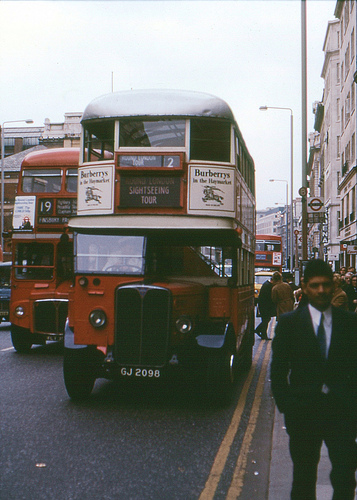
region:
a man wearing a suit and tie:
[287, 257, 348, 396]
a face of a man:
[308, 274, 330, 306]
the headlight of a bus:
[173, 313, 192, 336]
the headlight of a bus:
[86, 307, 105, 328]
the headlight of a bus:
[13, 304, 26, 317]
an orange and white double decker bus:
[67, 95, 247, 402]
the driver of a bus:
[97, 235, 146, 275]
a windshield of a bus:
[72, 230, 241, 278]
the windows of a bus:
[81, 116, 234, 162]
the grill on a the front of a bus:
[109, 284, 172, 369]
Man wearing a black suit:
[261, 248, 355, 498]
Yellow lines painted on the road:
[208, 400, 251, 498]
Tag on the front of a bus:
[113, 359, 162, 385]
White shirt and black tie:
[305, 301, 339, 357]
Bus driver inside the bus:
[67, 228, 148, 278]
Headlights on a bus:
[87, 300, 196, 338]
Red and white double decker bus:
[59, 102, 261, 409]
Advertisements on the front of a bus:
[76, 156, 237, 223]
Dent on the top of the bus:
[188, 104, 227, 115]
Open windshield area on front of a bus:
[79, 115, 122, 166]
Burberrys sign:
[188, 162, 239, 218]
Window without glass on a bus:
[81, 119, 119, 163]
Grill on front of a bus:
[106, 284, 179, 366]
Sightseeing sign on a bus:
[115, 166, 185, 209]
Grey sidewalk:
[276, 451, 288, 478]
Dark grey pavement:
[98, 428, 149, 482]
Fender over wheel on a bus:
[190, 313, 234, 350]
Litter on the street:
[248, 453, 263, 479]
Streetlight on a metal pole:
[268, 168, 292, 265]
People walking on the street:
[256, 266, 294, 347]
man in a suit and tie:
[261, 253, 355, 498]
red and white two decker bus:
[61, 80, 241, 449]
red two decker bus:
[4, 146, 69, 351]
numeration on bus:
[114, 360, 167, 380]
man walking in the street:
[250, 266, 286, 342]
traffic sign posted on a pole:
[303, 194, 327, 215]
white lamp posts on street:
[253, 99, 298, 195]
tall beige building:
[308, 53, 353, 269]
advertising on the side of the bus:
[12, 194, 37, 230]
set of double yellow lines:
[193, 332, 271, 498]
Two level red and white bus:
[59, 87, 254, 403]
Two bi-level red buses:
[8, 87, 255, 401]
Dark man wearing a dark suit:
[268, 257, 356, 499]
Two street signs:
[298, 186, 325, 214]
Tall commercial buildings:
[254, 0, 356, 278]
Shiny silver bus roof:
[80, 88, 237, 120]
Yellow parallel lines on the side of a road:
[195, 309, 274, 497]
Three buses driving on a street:
[0, 88, 284, 497]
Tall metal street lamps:
[258, 103, 294, 272]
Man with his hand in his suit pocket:
[270, 256, 352, 497]